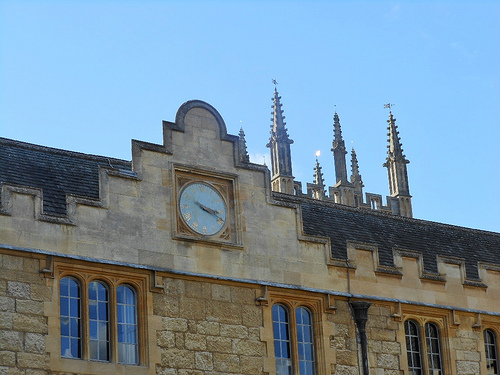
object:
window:
[60, 268, 86, 366]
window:
[87, 274, 114, 366]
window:
[114, 277, 141, 369]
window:
[272, 297, 293, 374]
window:
[294, 300, 321, 374]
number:
[198, 186, 206, 193]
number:
[178, 200, 190, 210]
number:
[181, 211, 193, 223]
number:
[187, 221, 199, 231]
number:
[180, 190, 192, 200]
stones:
[152, 276, 272, 373]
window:
[88, 273, 117, 361]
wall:
[1, 243, 498, 375]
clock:
[167, 160, 250, 251]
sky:
[1, 1, 499, 81]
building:
[241, 75, 413, 218]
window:
[292, 303, 317, 373]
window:
[269, 301, 294, 374]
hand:
[195, 201, 219, 217]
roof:
[0, 133, 500, 284]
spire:
[266, 72, 297, 142]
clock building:
[141, 94, 257, 265]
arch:
[57, 274, 84, 291]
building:
[0, 78, 500, 373]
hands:
[195, 201, 220, 214]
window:
[268, 300, 299, 375]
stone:
[457, 313, 479, 368]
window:
[57, 272, 84, 364]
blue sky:
[0, 0, 497, 80]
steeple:
[383, 104, 414, 217]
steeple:
[332, 110, 355, 208]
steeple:
[349, 145, 363, 203]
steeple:
[265, 88, 296, 194]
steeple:
[238, 127, 250, 162]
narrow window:
[293, 306, 320, 373]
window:
[404, 315, 425, 374]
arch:
[399, 312, 424, 326]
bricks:
[0, 151, 95, 187]